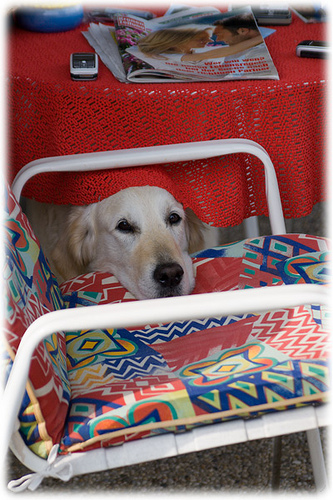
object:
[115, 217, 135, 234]
eye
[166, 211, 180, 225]
eye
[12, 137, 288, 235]
arm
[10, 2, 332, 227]
table cloth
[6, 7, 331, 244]
table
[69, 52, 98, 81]
phone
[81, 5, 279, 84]
magazines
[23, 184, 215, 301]
dog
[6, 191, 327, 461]
seat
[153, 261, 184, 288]
nose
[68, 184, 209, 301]
head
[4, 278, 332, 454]
arm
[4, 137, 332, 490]
chair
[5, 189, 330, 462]
cushion